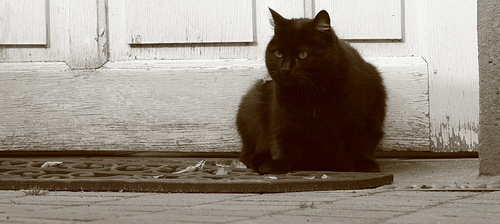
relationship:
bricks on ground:
[2, 180, 497, 221] [3, 187, 492, 222]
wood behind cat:
[13, 3, 479, 145] [245, 10, 400, 183]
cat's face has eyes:
[264, 33, 342, 88] [273, 49, 312, 62]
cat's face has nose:
[261, 10, 343, 86] [280, 62, 292, 74]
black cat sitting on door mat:
[214, 13, 409, 188] [4, 151, 412, 207]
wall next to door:
[475, 1, 498, 178] [0, 0, 475, 152]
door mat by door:
[0, 158, 395, 195] [0, 0, 475, 152]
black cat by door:
[235, 6, 390, 176] [0, 0, 475, 152]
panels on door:
[4, 2, 68, 62] [0, 0, 475, 152]